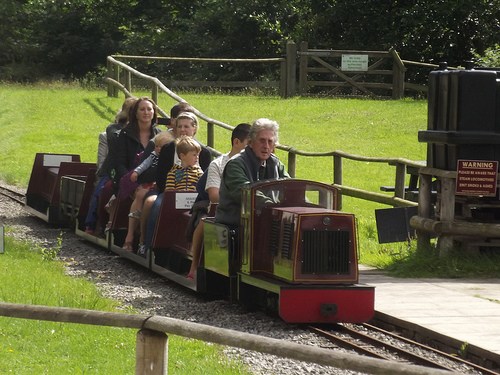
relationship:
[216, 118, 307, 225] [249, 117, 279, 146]
man has hair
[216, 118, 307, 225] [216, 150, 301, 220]
man wearing jacket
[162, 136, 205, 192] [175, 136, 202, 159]
boy has hair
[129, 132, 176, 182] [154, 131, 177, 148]
boy has hair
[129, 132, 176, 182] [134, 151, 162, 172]
boy wearing shirt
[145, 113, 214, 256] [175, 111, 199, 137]
woman has hair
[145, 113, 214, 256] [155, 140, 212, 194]
woman wearing jacket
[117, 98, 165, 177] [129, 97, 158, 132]
woman has hair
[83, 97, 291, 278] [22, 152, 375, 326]
people riding train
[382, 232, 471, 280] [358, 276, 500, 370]
weed next to platform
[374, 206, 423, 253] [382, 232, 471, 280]
sign posted near weed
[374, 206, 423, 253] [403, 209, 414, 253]
sign attached to post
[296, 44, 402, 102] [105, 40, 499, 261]
gate attached to fence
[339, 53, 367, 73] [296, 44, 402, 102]
sign hanging on gate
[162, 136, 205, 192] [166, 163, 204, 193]
boy wearing sweater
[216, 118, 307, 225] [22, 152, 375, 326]
man driving train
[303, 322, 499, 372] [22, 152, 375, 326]
train tracks under train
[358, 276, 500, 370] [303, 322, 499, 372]
platform next to train tracks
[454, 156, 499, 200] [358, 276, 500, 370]
sign behind platform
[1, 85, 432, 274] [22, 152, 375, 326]
area behind train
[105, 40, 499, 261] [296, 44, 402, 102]
fence has gate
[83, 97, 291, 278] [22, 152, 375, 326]
people on top of train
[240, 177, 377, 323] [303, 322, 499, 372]
train engine on top of train tracks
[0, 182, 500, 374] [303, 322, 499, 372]
gravel beside train tracks